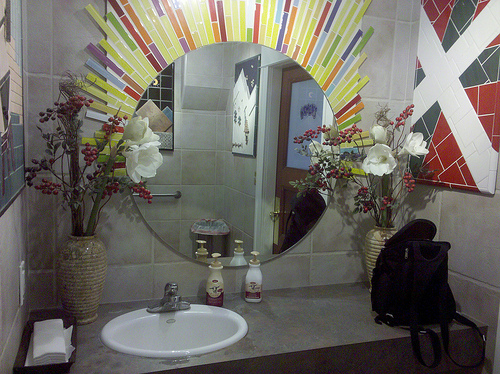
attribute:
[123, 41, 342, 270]
mirror — round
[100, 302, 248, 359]
sink — white, white color, off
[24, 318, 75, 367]
paper towels — stacked, napkin, white color, white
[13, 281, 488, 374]
counter top — silver, gray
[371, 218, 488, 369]
bag — black, black color, open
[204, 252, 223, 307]
soap — hand washing, cream color, pump bottle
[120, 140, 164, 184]
flower — white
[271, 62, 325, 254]
door — shut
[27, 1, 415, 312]
wall — light colored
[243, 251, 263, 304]
soap — white, white color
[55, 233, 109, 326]
vase — brownish tannish, decorative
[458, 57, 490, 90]
tile — decorative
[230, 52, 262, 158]
wall decoration — reflected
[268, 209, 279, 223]
door handle — brass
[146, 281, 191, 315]
faucet — chrome, silver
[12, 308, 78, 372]
rack — burgandy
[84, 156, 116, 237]
stem — green